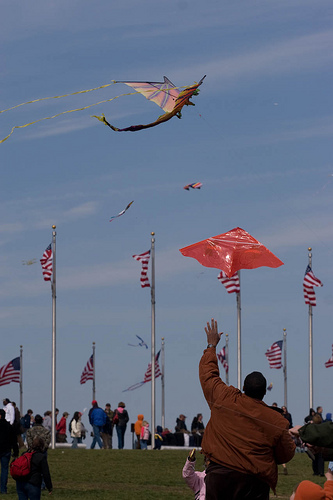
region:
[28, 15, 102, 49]
this is the sky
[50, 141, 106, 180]
the sky is blue in color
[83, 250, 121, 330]
the sky has some clouds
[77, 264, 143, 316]
the clouds are white in color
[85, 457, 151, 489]
this is the grass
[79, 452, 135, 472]
the grass is green in color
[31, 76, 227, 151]
this is a kite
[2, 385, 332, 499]
these are several people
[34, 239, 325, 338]
these are some flags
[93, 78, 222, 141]
the kite is in the air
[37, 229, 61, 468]
flag with metal post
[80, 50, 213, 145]
A kite is on the air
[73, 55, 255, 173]
Multi color kite with tail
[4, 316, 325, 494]
Lots of people watching kite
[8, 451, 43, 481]
A red color backpack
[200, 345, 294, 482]
A person wearing brown color jacket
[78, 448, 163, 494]
Green color grass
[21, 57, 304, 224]
A blue color sky with clouds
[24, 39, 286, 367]
Lots of kite in the air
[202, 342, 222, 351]
A watch in his hand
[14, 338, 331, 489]
many people enjoying a park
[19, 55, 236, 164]
large kite being flown in the air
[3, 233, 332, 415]
numerous American flags on silver poles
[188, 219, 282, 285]
small plastic red kite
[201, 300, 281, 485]
man reaching up to kite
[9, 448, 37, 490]
person with a red backpack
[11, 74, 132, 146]
yellow ribbons hanging from kite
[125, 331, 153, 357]
blue kite in the distance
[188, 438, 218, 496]
child with a pink jacket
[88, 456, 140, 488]
well manicured green lawn at park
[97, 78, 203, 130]
dragon kite in air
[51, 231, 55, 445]
grey metal flag pole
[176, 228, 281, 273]
red kite in air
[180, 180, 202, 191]
rainbow kite in air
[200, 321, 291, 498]
man with brown jacket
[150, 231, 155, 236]
gold ball on flag pole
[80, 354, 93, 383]
american flag on pole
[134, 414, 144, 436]
orange hooded winter jacket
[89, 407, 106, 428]
black and blue jacket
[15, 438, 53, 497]
child with red back pack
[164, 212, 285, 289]
A red kite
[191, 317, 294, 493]
A large man in a brown jacket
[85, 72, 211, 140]
A dragon shaped kite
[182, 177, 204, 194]
A rainbow colored kite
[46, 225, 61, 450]
A tall flag pole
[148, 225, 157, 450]
A tall flag pole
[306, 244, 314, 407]
A tall flag pole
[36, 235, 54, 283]
A waving American flag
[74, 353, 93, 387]
A waving American flag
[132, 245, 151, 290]
A waving American flag